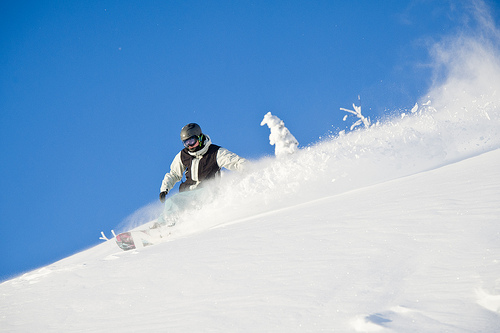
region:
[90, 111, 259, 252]
person riding a snowboard down a slope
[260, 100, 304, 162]
plume of white snow in the air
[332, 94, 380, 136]
plume of white snow in the air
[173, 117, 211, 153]
black helmet with pair of goggles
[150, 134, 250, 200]
white and black jacket on a person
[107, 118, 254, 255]
person on a snowboard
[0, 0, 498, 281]
clear blue daytime sky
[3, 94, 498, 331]
white snow on inclined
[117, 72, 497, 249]
spray of snow from snowboard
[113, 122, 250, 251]
person riding snowboard on slope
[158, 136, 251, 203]
black and white winter jacket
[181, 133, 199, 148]
goggles on person's face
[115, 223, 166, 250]
tip of tilted snowboard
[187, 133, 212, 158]
collar of winter coat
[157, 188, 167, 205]
black glove on hand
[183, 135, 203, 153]
a person wearing goggles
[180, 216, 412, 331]
the ground covered with snow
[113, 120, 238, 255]
a person skiing in the snow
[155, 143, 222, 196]
a person wearing a black and white coat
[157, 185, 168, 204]
a person wearing black gloves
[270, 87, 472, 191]
snow flying in the air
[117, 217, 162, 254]
a snowboard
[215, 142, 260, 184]
a person with their arm stretched out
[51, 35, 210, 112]
a clear blue sky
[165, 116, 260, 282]
Man is going down hill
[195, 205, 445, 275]
Snow is powder white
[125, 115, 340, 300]
Man skiing down hill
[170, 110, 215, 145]
Man wearing a helmet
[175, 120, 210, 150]
man wearing a goggles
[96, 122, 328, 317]
man skiing down hill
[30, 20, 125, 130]
Sky is bright blue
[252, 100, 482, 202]
Snow is flying everywhere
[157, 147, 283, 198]
man wearing a jacket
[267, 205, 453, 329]
ground covered in snow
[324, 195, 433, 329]
ground covered in white snow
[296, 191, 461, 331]
snow covering the ground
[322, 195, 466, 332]
white snow covering the ground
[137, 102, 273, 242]
a person is skiing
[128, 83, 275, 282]
a perosn is snowboarding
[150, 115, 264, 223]
a person wearing a helmet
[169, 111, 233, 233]
a person wearing a jacket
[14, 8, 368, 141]
a sky that is blue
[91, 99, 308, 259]
man skiing down the hill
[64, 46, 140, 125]
a view of sky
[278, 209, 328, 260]
a view of snow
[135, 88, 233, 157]
a view of helemt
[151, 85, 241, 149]
a view of cap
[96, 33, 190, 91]
a view of clouds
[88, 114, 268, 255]
Person on a snowboard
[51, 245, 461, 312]
Moutain covered with snow.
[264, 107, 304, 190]
Snow covered tree.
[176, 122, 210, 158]
Helmet on a snowboarder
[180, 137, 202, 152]
Person wearing ski goggles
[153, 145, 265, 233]
Black and white ski jacket